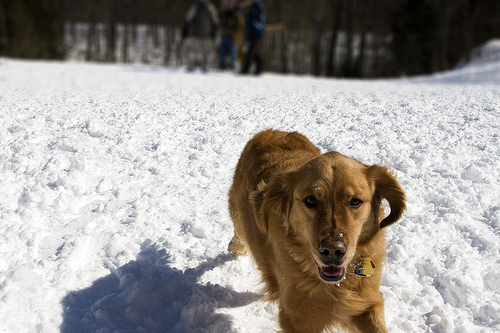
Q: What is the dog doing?
A: Looking at camera.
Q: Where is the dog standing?
A: In the snow.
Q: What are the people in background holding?
A: A snowboard.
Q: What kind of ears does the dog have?
A: Floppy.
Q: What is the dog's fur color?
A: Orange.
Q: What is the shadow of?
A: Dog.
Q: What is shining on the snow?
A: Sun.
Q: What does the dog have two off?
A: Ears.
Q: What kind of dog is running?
A: Golden dog.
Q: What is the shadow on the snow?
A: Dog.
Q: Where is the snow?
A: On the ground.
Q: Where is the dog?
A: In the snow.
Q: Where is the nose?
A: On the dog.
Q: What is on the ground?
A: Snow.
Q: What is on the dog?
A: Fur.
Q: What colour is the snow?
A: White.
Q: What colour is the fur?
A: Brown.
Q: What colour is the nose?
A: Brown.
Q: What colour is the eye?
A: Black.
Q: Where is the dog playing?
A: In the snow.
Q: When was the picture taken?
A: During the day.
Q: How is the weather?
A: Clear.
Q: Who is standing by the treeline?
A: People.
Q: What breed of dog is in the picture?
A: A Golden Retriever.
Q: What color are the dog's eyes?
A: Brown.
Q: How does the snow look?
A: Trampled upon.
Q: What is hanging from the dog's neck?
A: A tag.